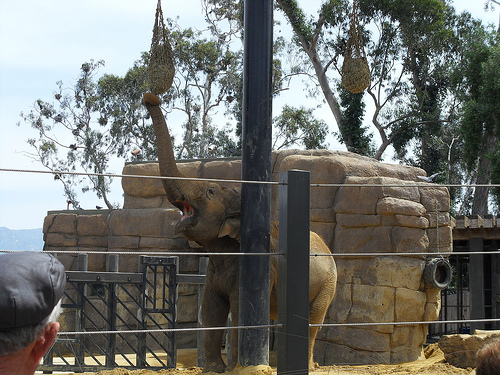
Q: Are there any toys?
A: No, there are no toys.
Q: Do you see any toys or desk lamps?
A: No, there are no toys or desk lamps.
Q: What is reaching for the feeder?
A: The trunk is reaching for the feeder.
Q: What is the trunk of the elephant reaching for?
A: The trunk is reaching for the feeder.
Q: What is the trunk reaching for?
A: The trunk is reaching for the feeder.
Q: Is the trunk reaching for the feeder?
A: Yes, the trunk is reaching for the feeder.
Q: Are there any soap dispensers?
A: No, there are no soap dispensers.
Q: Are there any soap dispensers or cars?
A: No, there are no soap dispensers or cars.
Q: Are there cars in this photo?
A: No, there are no cars.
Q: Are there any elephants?
A: Yes, there is an elephant.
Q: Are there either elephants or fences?
A: Yes, there is an elephant.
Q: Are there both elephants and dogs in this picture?
A: No, there is an elephant but no dogs.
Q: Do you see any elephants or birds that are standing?
A: Yes, the elephant is standing.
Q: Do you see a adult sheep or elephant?
A: Yes, there is an adult elephant.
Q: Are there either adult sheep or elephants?
A: Yes, there is an adult elephant.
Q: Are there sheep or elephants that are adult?
A: Yes, the elephant is adult.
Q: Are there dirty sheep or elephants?
A: Yes, there is a dirty elephant.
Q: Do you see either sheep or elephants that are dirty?
A: Yes, the elephant is dirty.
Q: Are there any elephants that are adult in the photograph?
A: Yes, there is an adult elephant.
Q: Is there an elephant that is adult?
A: Yes, there is an elephant that is adult.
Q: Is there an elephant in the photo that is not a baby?
A: Yes, there is a adult elephant.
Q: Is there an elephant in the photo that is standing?
A: Yes, there is an elephant that is standing.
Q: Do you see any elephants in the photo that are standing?
A: Yes, there is an elephant that is standing.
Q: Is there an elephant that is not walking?
A: Yes, there is an elephant that is standing.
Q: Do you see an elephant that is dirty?
A: Yes, there is a dirty elephant.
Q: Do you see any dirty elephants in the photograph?
A: Yes, there is a dirty elephant.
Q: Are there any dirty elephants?
A: Yes, there is a dirty elephant.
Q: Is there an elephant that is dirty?
A: Yes, there is an elephant that is dirty.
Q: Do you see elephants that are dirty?
A: Yes, there is an elephant that is dirty.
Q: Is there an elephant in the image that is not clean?
A: Yes, there is a dirty elephant.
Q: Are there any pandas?
A: No, there are no pandas.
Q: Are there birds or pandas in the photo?
A: No, there are no pandas or birds.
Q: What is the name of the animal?
A: The animal is an elephant.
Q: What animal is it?
A: The animal is an elephant.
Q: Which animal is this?
A: This is an elephant.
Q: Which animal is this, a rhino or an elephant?
A: This is an elephant.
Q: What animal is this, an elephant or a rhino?
A: This is an elephant.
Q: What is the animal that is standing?
A: The animal is an elephant.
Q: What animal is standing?
A: The animal is an elephant.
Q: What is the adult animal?
A: The animal is an elephant.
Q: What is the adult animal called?
A: The animal is an elephant.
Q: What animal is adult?
A: The animal is an elephant.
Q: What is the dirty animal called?
A: The animal is an elephant.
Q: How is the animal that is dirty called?
A: The animal is an elephant.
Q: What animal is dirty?
A: The animal is an elephant.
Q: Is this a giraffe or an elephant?
A: This is an elephant.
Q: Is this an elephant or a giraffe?
A: This is an elephant.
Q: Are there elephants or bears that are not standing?
A: No, there is an elephant but it is standing.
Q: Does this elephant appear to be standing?
A: Yes, the elephant is standing.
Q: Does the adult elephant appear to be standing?
A: Yes, the elephant is standing.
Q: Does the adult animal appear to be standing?
A: Yes, the elephant is standing.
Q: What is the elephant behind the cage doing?
A: The elephant is standing.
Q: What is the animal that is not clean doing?
A: The elephant is standing.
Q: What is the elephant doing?
A: The elephant is standing.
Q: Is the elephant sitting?
A: No, the elephant is standing.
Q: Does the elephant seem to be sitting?
A: No, the elephant is standing.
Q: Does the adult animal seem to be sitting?
A: No, the elephant is standing.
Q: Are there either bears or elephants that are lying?
A: No, there is an elephant but it is standing.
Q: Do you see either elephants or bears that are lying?
A: No, there is an elephant but it is standing.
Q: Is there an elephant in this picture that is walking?
A: No, there is an elephant but it is standing.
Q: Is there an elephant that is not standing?
A: No, there is an elephant but it is standing.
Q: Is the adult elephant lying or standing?
A: The elephant is standing.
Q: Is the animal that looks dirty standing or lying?
A: The elephant is standing.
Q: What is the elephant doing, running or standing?
A: The elephant is standing.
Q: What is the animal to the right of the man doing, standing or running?
A: The elephant is standing.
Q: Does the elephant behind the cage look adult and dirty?
A: Yes, the elephant is adult and dirty.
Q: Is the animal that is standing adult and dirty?
A: Yes, the elephant is adult and dirty.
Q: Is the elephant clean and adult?
A: No, the elephant is adult but dirty.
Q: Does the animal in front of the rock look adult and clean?
A: No, the elephant is adult but dirty.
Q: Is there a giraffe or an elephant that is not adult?
A: No, there is an elephant but it is adult.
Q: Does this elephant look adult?
A: Yes, the elephant is adult.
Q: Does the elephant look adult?
A: Yes, the elephant is adult.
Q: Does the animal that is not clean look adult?
A: Yes, the elephant is adult.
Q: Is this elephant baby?
A: No, the elephant is adult.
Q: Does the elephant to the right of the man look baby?
A: No, the elephant is adult.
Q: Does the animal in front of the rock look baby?
A: No, the elephant is adult.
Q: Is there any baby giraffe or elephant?
A: No, there is an elephant but it is adult.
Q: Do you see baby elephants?
A: No, there is an elephant but it is adult.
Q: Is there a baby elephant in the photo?
A: No, there is an elephant but it is adult.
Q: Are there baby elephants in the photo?
A: No, there is an elephant but it is adult.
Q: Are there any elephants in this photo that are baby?
A: No, there is an elephant but it is adult.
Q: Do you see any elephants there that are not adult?
A: No, there is an elephant but it is adult.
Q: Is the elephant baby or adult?
A: The elephant is adult.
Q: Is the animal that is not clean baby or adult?
A: The elephant is adult.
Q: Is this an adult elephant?
A: Yes, this is an adult elephant.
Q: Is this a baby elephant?
A: No, this is an adult elephant.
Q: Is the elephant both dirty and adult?
A: Yes, the elephant is dirty and adult.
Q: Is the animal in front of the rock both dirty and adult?
A: Yes, the elephant is dirty and adult.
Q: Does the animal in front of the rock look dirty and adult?
A: Yes, the elephant is dirty and adult.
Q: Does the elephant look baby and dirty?
A: No, the elephant is dirty but adult.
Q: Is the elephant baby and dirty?
A: No, the elephant is dirty but adult.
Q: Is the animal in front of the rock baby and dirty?
A: No, the elephant is dirty but adult.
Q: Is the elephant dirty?
A: Yes, the elephant is dirty.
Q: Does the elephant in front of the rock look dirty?
A: Yes, the elephant is dirty.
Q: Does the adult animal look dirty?
A: Yes, the elephant is dirty.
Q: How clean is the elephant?
A: The elephant is dirty.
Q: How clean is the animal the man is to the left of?
A: The elephant is dirty.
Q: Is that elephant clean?
A: No, the elephant is dirty.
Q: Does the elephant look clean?
A: No, the elephant is dirty.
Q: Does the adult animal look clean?
A: No, the elephant is dirty.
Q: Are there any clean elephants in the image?
A: No, there is an elephant but it is dirty.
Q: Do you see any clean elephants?
A: No, there is an elephant but it is dirty.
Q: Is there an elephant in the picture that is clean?
A: No, there is an elephant but it is dirty.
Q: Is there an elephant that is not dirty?
A: No, there is an elephant but it is dirty.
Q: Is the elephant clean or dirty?
A: The elephant is dirty.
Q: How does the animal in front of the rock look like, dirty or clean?
A: The elephant is dirty.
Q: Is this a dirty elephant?
A: Yes, this is a dirty elephant.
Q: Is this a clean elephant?
A: No, this is a dirty elephant.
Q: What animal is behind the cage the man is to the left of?
A: The animal is an elephant.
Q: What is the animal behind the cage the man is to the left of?
A: The animal is an elephant.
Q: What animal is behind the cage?
A: The animal is an elephant.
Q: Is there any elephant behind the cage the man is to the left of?
A: Yes, there is an elephant behind the cage.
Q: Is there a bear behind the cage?
A: No, there is an elephant behind the cage.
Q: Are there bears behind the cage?
A: No, there is an elephant behind the cage.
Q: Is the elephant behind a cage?
A: Yes, the elephant is behind a cage.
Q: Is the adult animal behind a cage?
A: Yes, the elephant is behind a cage.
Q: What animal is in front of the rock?
A: The elephant is in front of the rock.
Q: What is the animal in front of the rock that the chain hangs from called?
A: The animal is an elephant.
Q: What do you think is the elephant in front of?
A: The elephant is in front of the rock.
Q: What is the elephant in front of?
A: The elephant is in front of the rock.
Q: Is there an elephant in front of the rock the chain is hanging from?
A: Yes, there is an elephant in front of the rock.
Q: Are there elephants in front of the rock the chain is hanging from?
A: Yes, there is an elephant in front of the rock.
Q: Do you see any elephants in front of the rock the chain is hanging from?
A: Yes, there is an elephant in front of the rock.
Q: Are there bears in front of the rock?
A: No, there is an elephant in front of the rock.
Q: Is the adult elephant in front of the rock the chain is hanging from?
A: Yes, the elephant is in front of the rock.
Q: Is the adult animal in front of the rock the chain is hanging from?
A: Yes, the elephant is in front of the rock.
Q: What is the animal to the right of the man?
A: The animal is an elephant.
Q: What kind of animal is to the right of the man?
A: The animal is an elephant.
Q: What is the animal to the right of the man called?
A: The animal is an elephant.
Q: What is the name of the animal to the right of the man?
A: The animal is an elephant.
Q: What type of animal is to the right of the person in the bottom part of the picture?
A: The animal is an elephant.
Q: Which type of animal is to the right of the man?
A: The animal is an elephant.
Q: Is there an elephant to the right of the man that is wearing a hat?
A: Yes, there is an elephant to the right of the man.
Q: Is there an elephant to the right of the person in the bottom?
A: Yes, there is an elephant to the right of the man.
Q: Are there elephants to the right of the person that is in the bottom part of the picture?
A: Yes, there is an elephant to the right of the man.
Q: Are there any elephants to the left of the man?
A: No, the elephant is to the right of the man.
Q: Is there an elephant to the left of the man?
A: No, the elephant is to the right of the man.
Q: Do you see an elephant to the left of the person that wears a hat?
A: No, the elephant is to the right of the man.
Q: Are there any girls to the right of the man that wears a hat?
A: No, there is an elephant to the right of the man.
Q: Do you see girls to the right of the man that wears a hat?
A: No, there is an elephant to the right of the man.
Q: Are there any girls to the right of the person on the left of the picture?
A: No, there is an elephant to the right of the man.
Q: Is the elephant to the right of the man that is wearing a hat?
A: Yes, the elephant is to the right of the man.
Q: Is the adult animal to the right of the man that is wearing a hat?
A: Yes, the elephant is to the right of the man.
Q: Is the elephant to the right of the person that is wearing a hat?
A: Yes, the elephant is to the right of the man.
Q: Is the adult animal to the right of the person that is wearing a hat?
A: Yes, the elephant is to the right of the man.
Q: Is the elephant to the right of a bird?
A: No, the elephant is to the right of the man.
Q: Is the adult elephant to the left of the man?
A: No, the elephant is to the right of the man.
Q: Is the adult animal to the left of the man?
A: No, the elephant is to the right of the man.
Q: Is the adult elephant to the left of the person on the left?
A: No, the elephant is to the right of the man.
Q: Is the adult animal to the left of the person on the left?
A: No, the elephant is to the right of the man.